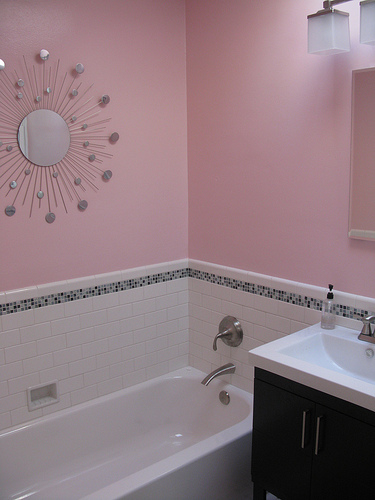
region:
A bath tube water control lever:
[205, 310, 248, 357]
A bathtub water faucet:
[197, 353, 245, 394]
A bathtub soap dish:
[19, 372, 66, 414]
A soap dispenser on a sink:
[315, 271, 340, 333]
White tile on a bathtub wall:
[162, 283, 204, 311]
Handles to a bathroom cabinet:
[287, 400, 332, 469]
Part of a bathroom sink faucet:
[358, 307, 374, 345]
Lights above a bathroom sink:
[303, 0, 373, 60]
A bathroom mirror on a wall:
[331, 63, 373, 252]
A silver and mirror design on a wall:
[1, 37, 136, 251]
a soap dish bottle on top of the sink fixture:
[321, 284, 336, 329]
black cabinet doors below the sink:
[250, 378, 373, 499]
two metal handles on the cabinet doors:
[300, 410, 322, 456]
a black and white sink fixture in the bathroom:
[247, 320, 373, 498]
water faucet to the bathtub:
[212, 314, 243, 350]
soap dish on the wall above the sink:
[27, 378, 59, 411]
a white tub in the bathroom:
[0, 367, 252, 499]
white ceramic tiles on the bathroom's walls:
[72, 301, 162, 375]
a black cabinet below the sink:
[251, 368, 373, 498]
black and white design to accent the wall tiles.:
[0, 267, 319, 316]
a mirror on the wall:
[11, 27, 228, 297]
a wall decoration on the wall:
[18, 29, 192, 235]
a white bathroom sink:
[207, 296, 374, 428]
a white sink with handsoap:
[262, 268, 373, 430]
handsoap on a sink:
[296, 261, 372, 445]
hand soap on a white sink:
[287, 263, 372, 389]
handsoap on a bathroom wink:
[258, 269, 365, 415]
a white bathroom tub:
[19, 301, 284, 497]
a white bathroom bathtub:
[35, 337, 332, 496]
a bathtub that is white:
[3, 343, 283, 499]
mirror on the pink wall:
[10, 104, 81, 169]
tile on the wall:
[77, 309, 112, 328]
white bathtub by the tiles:
[0, 364, 254, 498]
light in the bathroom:
[303, 7, 351, 57]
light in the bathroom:
[356, 1, 373, 45]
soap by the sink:
[311, 273, 338, 331]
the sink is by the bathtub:
[246, 307, 370, 498]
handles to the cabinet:
[297, 406, 325, 464]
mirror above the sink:
[343, 66, 371, 246]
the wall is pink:
[203, 121, 231, 162]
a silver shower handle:
[201, 307, 248, 357]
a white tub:
[91, 359, 251, 498]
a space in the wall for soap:
[9, 373, 77, 429]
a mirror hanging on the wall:
[10, 43, 137, 241]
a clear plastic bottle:
[312, 280, 344, 337]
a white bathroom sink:
[282, 312, 367, 412]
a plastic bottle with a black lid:
[313, 276, 345, 344]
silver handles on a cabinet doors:
[287, 402, 344, 464]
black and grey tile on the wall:
[29, 257, 209, 331]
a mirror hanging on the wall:
[337, 68, 369, 287]